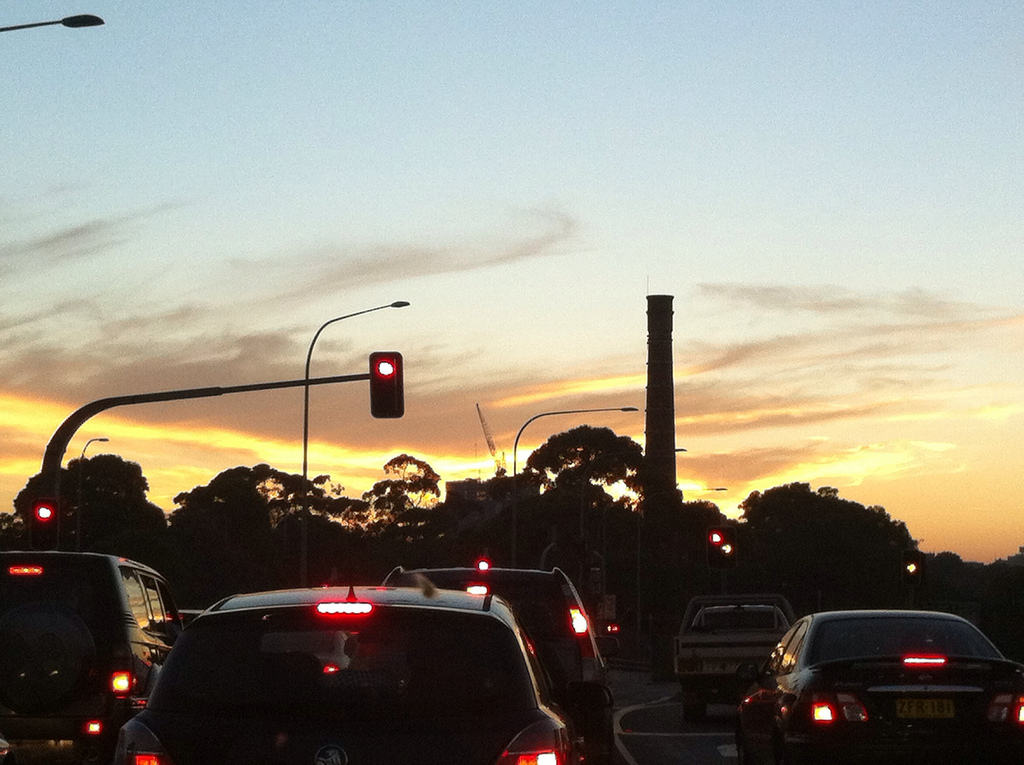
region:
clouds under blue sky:
[0, 3, 1019, 553]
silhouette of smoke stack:
[641, 292, 677, 501]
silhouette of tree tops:
[1, 421, 1020, 603]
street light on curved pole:
[303, 300, 409, 484]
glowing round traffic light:
[369, 351, 405, 419]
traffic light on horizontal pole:
[42, 351, 403, 468]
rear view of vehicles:
[1, 553, 1017, 760]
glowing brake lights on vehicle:
[138, 599, 566, 761]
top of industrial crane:
[474, 403, 503, 474]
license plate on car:
[888, 687, 961, 725]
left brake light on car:
[800, 687, 839, 733]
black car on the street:
[726, 599, 1020, 756]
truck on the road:
[669, 584, 803, 720]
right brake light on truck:
[558, 593, 598, 645]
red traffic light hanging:
[367, 337, 409, 423]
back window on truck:
[160, 608, 525, 720]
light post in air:
[0, 6, 114, 51]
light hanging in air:
[379, 296, 415, 322]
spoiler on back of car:
[808, 647, 1023, 680]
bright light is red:
[376, 359, 393, 378]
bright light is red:
[316, 600, 374, 617]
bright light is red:
[134, 747, 158, 761]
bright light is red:
[105, 666, 132, 690]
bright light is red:
[86, 717, 100, 736]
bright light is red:
[30, 502, 53, 519]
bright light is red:
[10, 561, 42, 574]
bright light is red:
[566, 603, 590, 633]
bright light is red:
[477, 556, 491, 570]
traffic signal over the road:
[364, 341, 410, 421]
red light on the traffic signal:
[378, 352, 385, 372]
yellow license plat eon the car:
[895, 695, 962, 722]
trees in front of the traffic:
[28, 380, 1021, 669]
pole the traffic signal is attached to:
[40, 371, 370, 499]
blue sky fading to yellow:
[7, 13, 1022, 558]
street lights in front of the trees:
[287, 284, 643, 550]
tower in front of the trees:
[639, 282, 679, 529]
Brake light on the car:
[806, 691, 832, 727]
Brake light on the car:
[1018, 701, 1022, 733]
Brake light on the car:
[903, 647, 943, 664]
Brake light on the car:
[306, 593, 382, 617]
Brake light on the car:
[568, 603, 594, 636]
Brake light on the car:
[107, 664, 142, 697]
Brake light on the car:
[82, 718, 111, 738]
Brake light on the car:
[10, 557, 40, 581]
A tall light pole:
[298, 299, 413, 585]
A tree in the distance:
[11, 453, 170, 559]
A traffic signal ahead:
[700, 522, 740, 586]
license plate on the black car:
[887, 687, 965, 717]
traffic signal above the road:
[358, 343, 407, 411]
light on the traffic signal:
[370, 360, 399, 380]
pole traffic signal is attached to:
[48, 374, 358, 545]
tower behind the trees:
[639, 288, 682, 510]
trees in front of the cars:
[18, 414, 913, 627]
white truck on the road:
[661, 586, 805, 711]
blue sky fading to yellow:
[4, 6, 1022, 538]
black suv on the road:
[3, 538, 174, 735]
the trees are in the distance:
[210, 441, 872, 610]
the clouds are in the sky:
[21, 313, 968, 501]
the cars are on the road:
[23, 512, 948, 712]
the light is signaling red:
[364, 354, 403, 418]